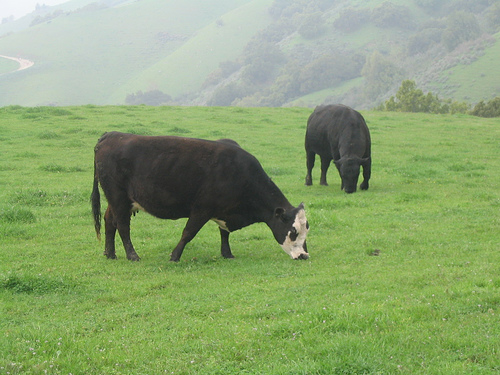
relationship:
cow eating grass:
[294, 100, 391, 209] [335, 196, 390, 225]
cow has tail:
[294, 100, 391, 209] [88, 141, 109, 235]